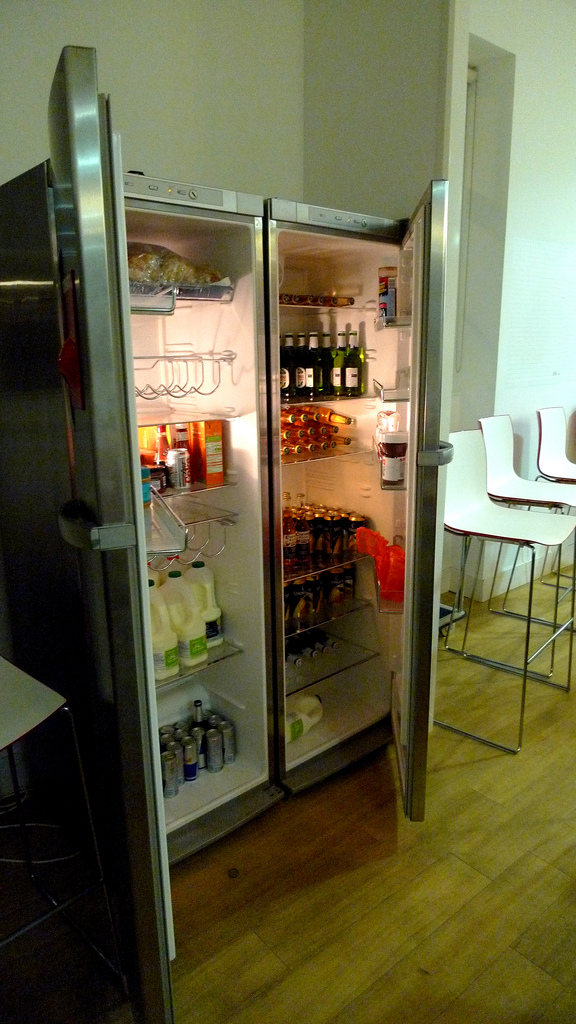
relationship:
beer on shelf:
[159, 699, 236, 797] [156, 723, 265, 825]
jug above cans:
[148, 561, 224, 681] [155, 692, 233, 798]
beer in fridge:
[159, 699, 236, 797] [9, 149, 473, 844]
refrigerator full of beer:
[4, 140, 465, 956] [277, 322, 369, 671]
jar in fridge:
[379, 431, 406, 486] [4, 120, 467, 905]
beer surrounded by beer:
[186, 696, 212, 743] [159, 699, 236, 797]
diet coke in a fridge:
[167, 447, 191, 490] [0, 170, 449, 880]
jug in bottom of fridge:
[285, 690, 324, 741] [3, 45, 447, 1020]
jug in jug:
[148, 561, 224, 681] [142, 570, 228, 674]